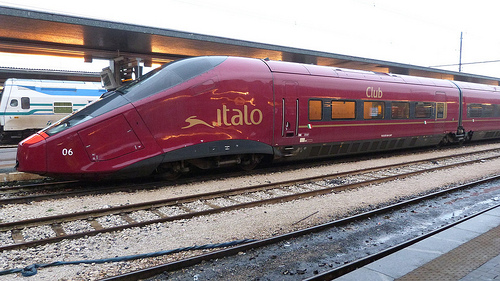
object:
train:
[13, 55, 499, 182]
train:
[0, 77, 110, 130]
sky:
[329, 17, 358, 37]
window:
[114, 56, 228, 102]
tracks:
[208, 189, 227, 199]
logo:
[211, 104, 264, 127]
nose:
[20, 71, 168, 149]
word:
[364, 86, 372, 98]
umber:
[51, 158, 80, 165]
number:
[61, 147, 69, 156]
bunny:
[180, 115, 215, 130]